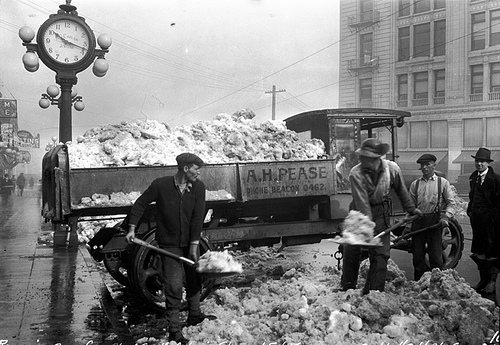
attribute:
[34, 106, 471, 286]
truck — old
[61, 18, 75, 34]
number — black, print style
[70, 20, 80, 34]
number — print style, black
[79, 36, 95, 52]
number — black, print style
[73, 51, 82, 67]
number — print style, black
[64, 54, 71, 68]
number — black, print style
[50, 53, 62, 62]
number — print style, black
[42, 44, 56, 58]
number — black, print style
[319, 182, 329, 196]
number — black, print style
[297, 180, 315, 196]
number — print style, black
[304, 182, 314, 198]
number — black, print style